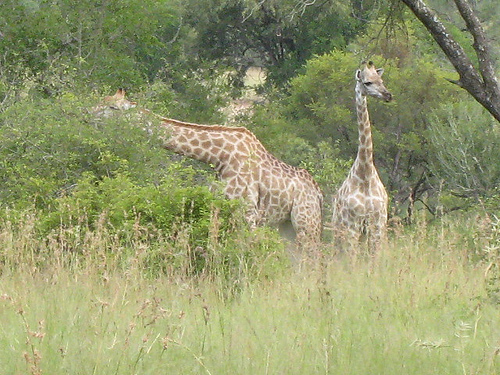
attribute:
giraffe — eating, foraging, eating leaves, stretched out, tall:
[92, 93, 326, 267]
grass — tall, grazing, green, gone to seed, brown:
[9, 208, 499, 372]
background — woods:
[0, 2, 499, 191]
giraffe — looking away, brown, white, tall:
[331, 59, 393, 258]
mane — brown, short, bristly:
[131, 101, 248, 134]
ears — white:
[350, 64, 388, 82]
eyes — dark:
[361, 79, 379, 91]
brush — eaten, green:
[0, 76, 140, 189]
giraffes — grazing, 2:
[84, 61, 395, 261]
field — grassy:
[4, 3, 496, 372]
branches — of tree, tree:
[404, 0, 500, 122]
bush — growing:
[37, 179, 285, 306]